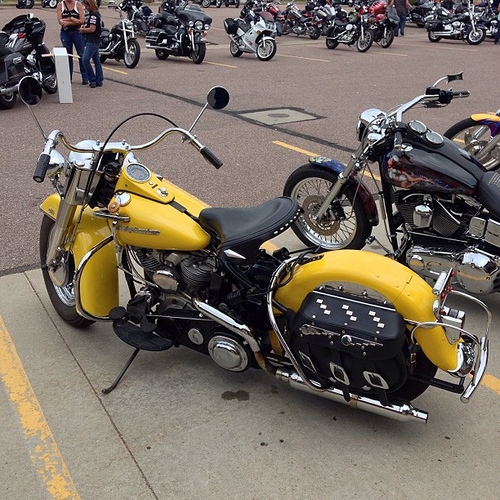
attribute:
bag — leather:
[244, 249, 454, 397]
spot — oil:
[199, 377, 283, 433]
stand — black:
[85, 335, 191, 438]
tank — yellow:
[91, 145, 219, 237]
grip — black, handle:
[31, 150, 51, 187]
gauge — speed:
[121, 158, 153, 187]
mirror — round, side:
[202, 82, 232, 116]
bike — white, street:
[220, 12, 283, 59]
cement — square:
[225, 94, 331, 138]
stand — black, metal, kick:
[101, 341, 141, 397]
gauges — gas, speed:
[407, 119, 446, 149]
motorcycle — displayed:
[5, 15, 72, 133]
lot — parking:
[13, 12, 484, 498]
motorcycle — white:
[224, 5, 279, 62]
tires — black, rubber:
[226, 36, 276, 60]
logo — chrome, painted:
[113, 222, 159, 239]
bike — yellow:
[9, 68, 481, 433]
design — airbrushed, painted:
[386, 166, 463, 202]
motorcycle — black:
[280, 79, 484, 305]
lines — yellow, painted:
[115, 62, 242, 78]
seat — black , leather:
[197, 190, 305, 257]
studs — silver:
[274, 204, 300, 234]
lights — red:
[440, 267, 459, 307]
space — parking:
[23, 210, 477, 452]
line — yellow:
[4, 342, 78, 488]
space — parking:
[5, 280, 362, 497]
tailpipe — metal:
[264, 366, 437, 426]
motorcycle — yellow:
[11, 74, 484, 449]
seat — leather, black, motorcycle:
[197, 193, 302, 261]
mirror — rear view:
[188, 80, 232, 133]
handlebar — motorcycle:
[128, 123, 226, 183]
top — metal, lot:
[269, 110, 292, 120]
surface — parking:
[245, 96, 321, 137]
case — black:
[290, 277, 425, 405]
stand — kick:
[102, 333, 152, 410]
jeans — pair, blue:
[76, 40, 107, 87]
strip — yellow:
[22, 396, 65, 500]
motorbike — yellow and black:
[55, 223, 411, 295]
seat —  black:
[214, 173, 288, 297]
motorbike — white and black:
[240, 51, 273, 79]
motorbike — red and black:
[392, 51, 398, 67]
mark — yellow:
[27, 405, 51, 500]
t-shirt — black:
[86, 10, 100, 40]